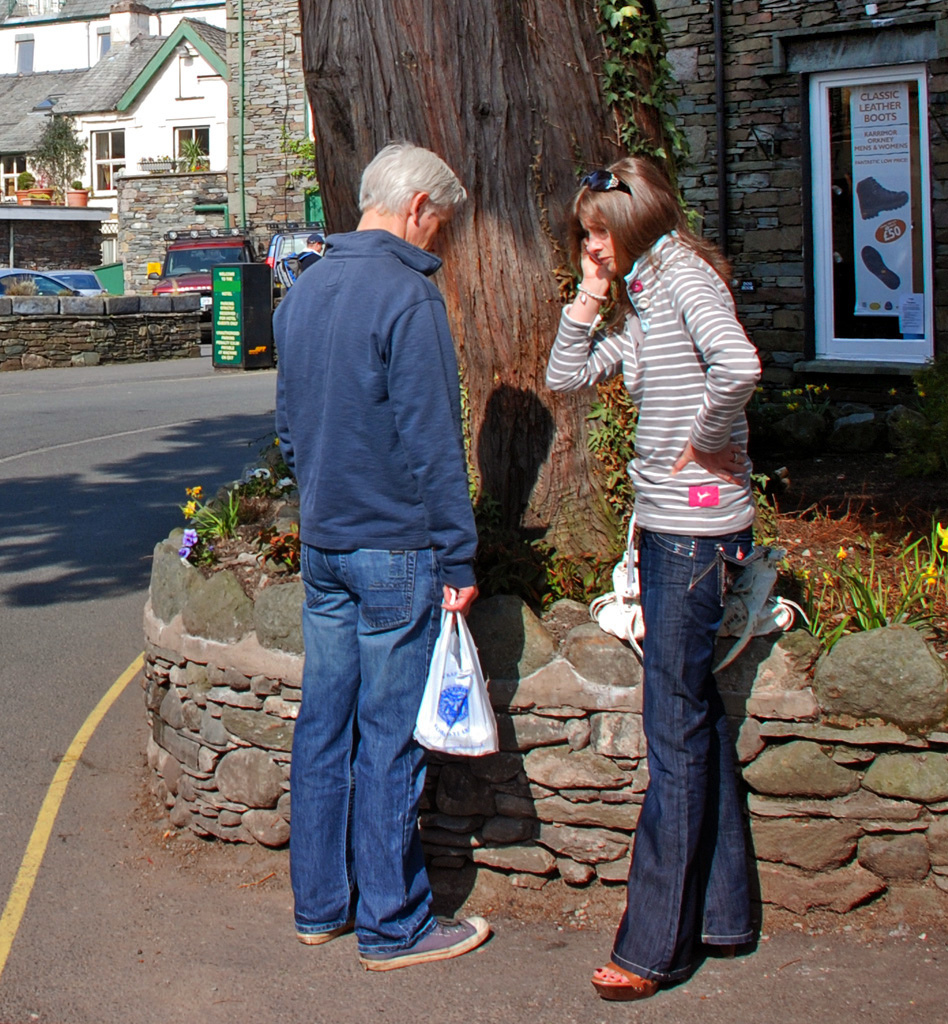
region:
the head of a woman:
[539, 179, 677, 294]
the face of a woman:
[568, 211, 639, 292]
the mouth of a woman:
[568, 233, 623, 281]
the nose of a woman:
[572, 221, 609, 281]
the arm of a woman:
[503, 291, 674, 469]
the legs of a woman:
[556, 569, 769, 998]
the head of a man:
[324, 150, 487, 258]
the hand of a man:
[422, 558, 501, 644]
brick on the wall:
[808, 869, 844, 890]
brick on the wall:
[785, 825, 839, 861]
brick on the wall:
[786, 788, 868, 821]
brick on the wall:
[861, 813, 915, 830]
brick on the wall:
[522, 719, 562, 742]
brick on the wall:
[494, 842, 556, 882]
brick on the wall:
[525, 823, 599, 855]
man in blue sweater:
[262, 125, 517, 986]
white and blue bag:
[401, 588, 502, 764]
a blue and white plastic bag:
[404, 576, 502, 760]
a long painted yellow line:
[0, 643, 158, 969]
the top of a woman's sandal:
[589, 958, 666, 1006]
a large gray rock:
[817, 622, 944, 726]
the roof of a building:
[62, 33, 156, 119]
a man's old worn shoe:
[357, 916, 493, 968]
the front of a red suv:
[157, 225, 258, 311]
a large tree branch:
[222, 0, 663, 555]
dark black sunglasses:
[575, 169, 634, 197]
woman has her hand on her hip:
[627, 221, 784, 546]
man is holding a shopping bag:
[386, 515, 512, 773]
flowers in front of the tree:
[169, 435, 351, 624]